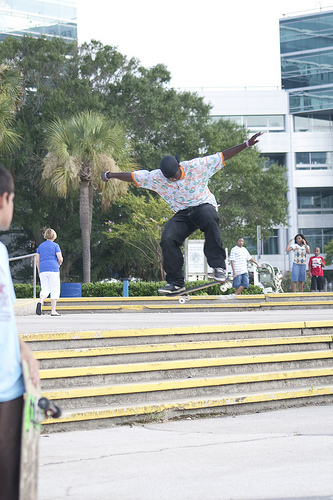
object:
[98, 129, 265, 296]
man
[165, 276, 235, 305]
skateboard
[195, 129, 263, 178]
arm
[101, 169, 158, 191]
arm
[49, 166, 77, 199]
palm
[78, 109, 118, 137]
palm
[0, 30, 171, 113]
tree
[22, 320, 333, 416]
steps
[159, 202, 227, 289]
pants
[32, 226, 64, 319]
woman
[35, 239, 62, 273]
shirt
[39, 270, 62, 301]
pants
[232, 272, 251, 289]
shorts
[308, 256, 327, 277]
shirt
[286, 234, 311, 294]
woman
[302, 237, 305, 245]
phone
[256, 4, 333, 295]
building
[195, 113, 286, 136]
windows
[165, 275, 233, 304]
wheels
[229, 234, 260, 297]
boy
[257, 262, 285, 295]
stroller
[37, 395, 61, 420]
wheel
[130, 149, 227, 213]
shirt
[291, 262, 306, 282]
shorts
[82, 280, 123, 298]
bushes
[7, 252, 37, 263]
handrail